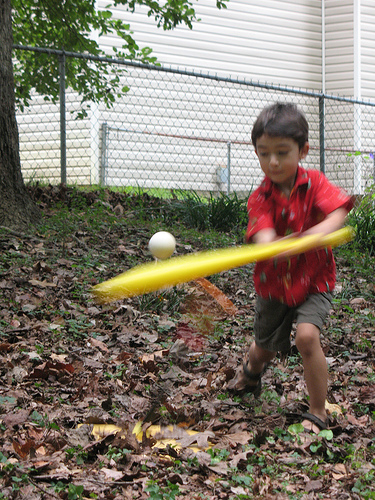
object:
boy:
[232, 102, 354, 421]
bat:
[92, 225, 352, 301]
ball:
[149, 230, 178, 262]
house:
[11, 41, 373, 194]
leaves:
[10, 438, 35, 462]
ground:
[0, 298, 244, 500]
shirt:
[244, 167, 350, 304]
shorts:
[252, 296, 331, 354]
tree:
[0, 0, 188, 193]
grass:
[64, 181, 246, 229]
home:
[22, 1, 373, 184]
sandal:
[296, 409, 326, 441]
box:
[212, 165, 228, 185]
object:
[76, 419, 206, 458]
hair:
[250, 102, 311, 146]